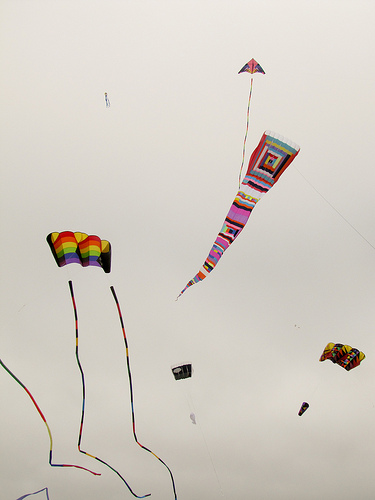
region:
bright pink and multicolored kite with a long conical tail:
[165, 115, 313, 299]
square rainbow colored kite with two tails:
[35, 216, 133, 282]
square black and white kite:
[159, 353, 210, 432]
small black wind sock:
[295, 388, 316, 426]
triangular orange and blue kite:
[214, 38, 282, 85]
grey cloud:
[139, 29, 220, 126]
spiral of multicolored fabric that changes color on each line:
[248, 144, 295, 178]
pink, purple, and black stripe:
[227, 203, 254, 225]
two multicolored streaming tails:
[60, 275, 174, 496]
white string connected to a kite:
[292, 162, 373, 259]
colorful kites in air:
[20, 33, 366, 469]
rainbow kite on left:
[35, 227, 156, 420]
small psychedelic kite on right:
[278, 338, 374, 460]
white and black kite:
[160, 349, 211, 436]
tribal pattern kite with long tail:
[185, 125, 276, 331]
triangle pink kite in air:
[215, 43, 273, 101]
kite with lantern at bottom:
[286, 398, 313, 426]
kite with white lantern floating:
[156, 348, 201, 449]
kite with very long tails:
[41, 230, 169, 490]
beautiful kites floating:
[15, 77, 341, 443]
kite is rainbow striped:
[43, 231, 119, 269]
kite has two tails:
[64, 278, 177, 498]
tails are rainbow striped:
[65, 278, 181, 498]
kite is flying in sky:
[45, 230, 182, 497]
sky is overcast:
[4, 1, 373, 498]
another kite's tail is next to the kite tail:
[0, 361, 104, 478]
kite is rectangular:
[47, 231, 114, 269]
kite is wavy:
[41, 228, 114, 276]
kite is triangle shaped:
[237, 57, 264, 78]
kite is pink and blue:
[239, 55, 265, 78]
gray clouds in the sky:
[89, 155, 191, 194]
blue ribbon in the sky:
[17, 484, 52, 497]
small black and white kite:
[161, 361, 223, 384]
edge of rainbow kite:
[175, 284, 192, 310]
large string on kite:
[60, 284, 95, 408]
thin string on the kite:
[172, 383, 235, 399]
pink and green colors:
[226, 226, 247, 250]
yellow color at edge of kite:
[53, 222, 117, 248]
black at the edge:
[103, 254, 120, 291]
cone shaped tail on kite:
[286, 392, 328, 434]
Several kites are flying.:
[3, 48, 368, 498]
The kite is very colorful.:
[160, 129, 313, 306]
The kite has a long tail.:
[167, 176, 265, 304]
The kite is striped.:
[43, 217, 121, 276]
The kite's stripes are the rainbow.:
[37, 221, 133, 278]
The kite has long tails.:
[60, 266, 186, 497]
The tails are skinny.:
[46, 272, 197, 498]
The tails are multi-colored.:
[58, 263, 178, 498]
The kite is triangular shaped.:
[227, 51, 277, 83]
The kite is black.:
[162, 357, 212, 382]